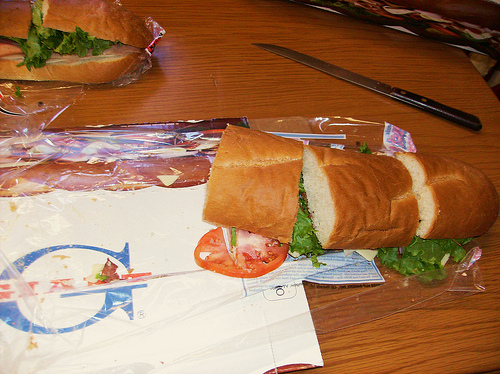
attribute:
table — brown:
[213, 51, 240, 95]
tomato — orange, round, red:
[183, 218, 295, 288]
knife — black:
[245, 28, 489, 135]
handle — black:
[393, 82, 484, 134]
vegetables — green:
[26, 31, 93, 59]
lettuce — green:
[396, 244, 440, 275]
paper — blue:
[74, 237, 142, 260]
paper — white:
[96, 202, 158, 228]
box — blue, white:
[39, 320, 82, 335]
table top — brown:
[172, 22, 235, 99]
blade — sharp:
[250, 33, 384, 103]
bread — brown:
[431, 2, 496, 19]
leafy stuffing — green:
[291, 212, 317, 258]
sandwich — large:
[6, 5, 151, 82]